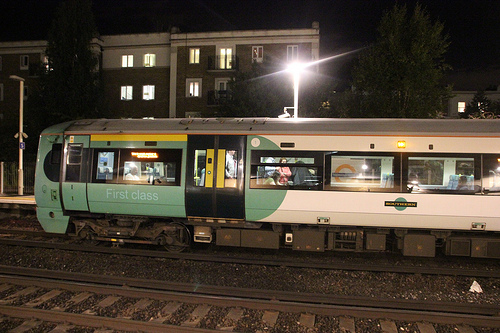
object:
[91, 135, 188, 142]
strip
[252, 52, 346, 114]
light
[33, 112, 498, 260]
train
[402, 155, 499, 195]
window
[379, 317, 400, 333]
cross tie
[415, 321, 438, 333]
cross tie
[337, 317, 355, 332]
cross tie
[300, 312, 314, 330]
cross tie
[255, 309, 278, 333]
cross tie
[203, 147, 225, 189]
strip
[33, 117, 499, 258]
bus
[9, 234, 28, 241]
strip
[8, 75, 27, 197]
streetlight off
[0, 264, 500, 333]
track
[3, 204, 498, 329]
gravel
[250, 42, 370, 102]
bright light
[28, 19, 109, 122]
tree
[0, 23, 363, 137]
building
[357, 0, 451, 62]
leaves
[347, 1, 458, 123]
tree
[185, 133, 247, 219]
door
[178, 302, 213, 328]
cross tie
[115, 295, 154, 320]
cross tie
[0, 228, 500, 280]
track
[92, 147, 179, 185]
windows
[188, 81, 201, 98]
windows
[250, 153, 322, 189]
windows